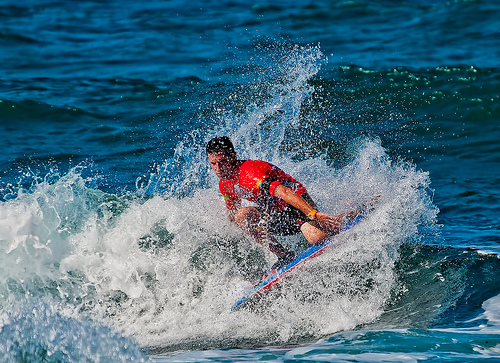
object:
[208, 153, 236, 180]
face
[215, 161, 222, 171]
nose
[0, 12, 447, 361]
water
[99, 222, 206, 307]
splashes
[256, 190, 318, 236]
black short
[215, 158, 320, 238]
wetsuit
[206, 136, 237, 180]
head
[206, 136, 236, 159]
black hair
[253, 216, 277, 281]
thread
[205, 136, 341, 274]
man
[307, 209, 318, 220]
clock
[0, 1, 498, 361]
ocean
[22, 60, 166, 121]
water ripples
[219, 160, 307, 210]
shirt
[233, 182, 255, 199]
design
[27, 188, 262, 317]
wave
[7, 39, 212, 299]
sea foam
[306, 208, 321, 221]
left wrist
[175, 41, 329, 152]
white spray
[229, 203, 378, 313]
surfboard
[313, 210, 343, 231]
hand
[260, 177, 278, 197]
stripe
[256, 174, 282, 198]
sleeve